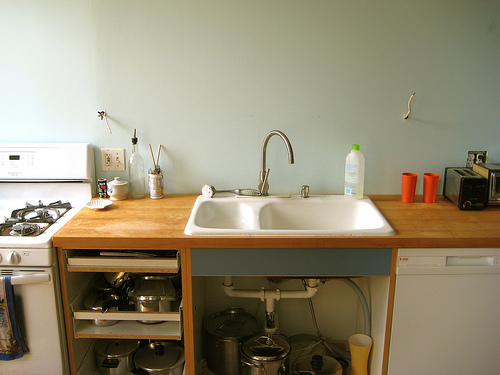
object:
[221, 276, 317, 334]
pipe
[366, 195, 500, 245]
counter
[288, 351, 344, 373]
pots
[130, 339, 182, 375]
pots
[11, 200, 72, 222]
burner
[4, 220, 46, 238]
burner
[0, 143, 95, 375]
gas stove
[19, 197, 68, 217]
burner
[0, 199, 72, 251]
stove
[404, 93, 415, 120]
wire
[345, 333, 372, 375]
cup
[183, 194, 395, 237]
kitchen sink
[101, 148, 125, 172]
outlet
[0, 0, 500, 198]
wall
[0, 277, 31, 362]
towel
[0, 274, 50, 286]
handle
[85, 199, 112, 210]
small dish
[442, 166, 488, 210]
toaster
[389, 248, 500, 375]
dishwasher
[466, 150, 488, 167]
wall outlet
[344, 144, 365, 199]
bottle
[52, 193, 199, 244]
counter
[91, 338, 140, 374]
pot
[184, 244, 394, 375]
cabinet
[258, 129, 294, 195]
faucet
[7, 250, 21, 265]
knob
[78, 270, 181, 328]
pots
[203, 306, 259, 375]
pot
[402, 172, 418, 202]
cup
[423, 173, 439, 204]
cup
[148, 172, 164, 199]
container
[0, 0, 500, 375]
kitchen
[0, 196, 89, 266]
counter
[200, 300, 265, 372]
pots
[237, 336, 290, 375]
pots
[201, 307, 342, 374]
pots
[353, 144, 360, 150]
cap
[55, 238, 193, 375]
cabinet